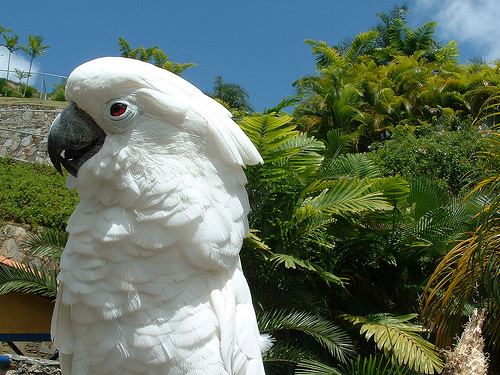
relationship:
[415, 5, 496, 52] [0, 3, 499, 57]
clouds in sky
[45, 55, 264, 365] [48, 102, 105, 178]
parrot has beak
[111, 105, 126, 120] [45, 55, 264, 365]
eye of parrot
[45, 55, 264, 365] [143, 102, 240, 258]
parrot has feathers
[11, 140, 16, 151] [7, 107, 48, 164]
stone in wall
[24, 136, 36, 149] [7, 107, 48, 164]
stone in wall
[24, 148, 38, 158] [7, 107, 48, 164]
stone in wall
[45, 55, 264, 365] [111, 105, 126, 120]
parrot has eye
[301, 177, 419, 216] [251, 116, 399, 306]
leaves of palm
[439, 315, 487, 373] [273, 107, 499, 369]
straw near bushes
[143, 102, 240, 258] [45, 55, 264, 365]
feathers on parrot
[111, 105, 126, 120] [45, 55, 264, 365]
eye belongs to parrot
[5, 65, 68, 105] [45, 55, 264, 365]
fence behind parrot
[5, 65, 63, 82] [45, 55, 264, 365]
rail behind parrot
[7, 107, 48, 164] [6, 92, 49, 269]
wall on hillside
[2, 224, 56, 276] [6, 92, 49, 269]
wall on hillside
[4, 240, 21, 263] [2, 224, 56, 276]
rock in wall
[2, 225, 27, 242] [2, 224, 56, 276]
rock in wall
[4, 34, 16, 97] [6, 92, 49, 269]
palm on hill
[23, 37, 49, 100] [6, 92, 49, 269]
palm on hill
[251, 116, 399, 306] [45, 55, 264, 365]
palm behind parrot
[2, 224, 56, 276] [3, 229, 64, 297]
wall under bushes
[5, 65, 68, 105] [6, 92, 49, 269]
fence on hillside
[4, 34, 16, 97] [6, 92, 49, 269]
palm on top of hill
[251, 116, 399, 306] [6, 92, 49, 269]
palm on top of hill